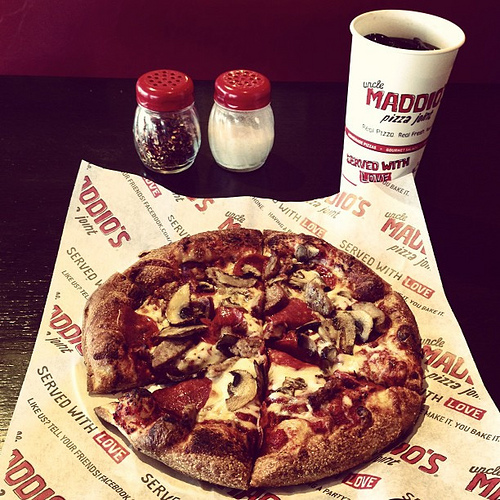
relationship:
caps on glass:
[134, 66, 276, 115] [126, 108, 286, 181]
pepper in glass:
[136, 112, 198, 170] [126, 108, 286, 181]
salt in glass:
[211, 106, 270, 167] [126, 108, 286, 181]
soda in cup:
[365, 31, 455, 51] [341, 5, 470, 213]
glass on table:
[126, 108, 286, 181] [1, 78, 500, 499]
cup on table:
[341, 5, 470, 213] [1, 78, 500, 499]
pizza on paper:
[82, 238, 446, 490] [32, 156, 498, 492]